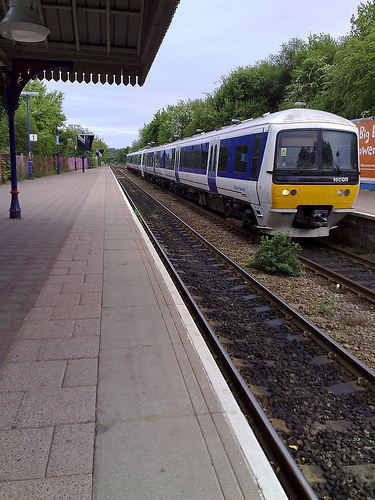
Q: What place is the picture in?
A: It is at the station.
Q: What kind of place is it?
A: It is a station.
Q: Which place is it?
A: It is a station.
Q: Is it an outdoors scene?
A: Yes, it is outdoors.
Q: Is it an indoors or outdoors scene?
A: It is outdoors.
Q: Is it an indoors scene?
A: No, it is outdoors.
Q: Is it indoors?
A: No, it is outdoors.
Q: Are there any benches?
A: No, there are no benches.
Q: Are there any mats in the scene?
A: No, there are no mats.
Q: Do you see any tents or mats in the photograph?
A: No, there are no mats or tents.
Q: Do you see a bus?
A: No, there are no buses.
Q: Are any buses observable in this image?
A: No, there are no buses.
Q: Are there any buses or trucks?
A: No, there are no buses or trucks.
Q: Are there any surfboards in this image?
A: No, there are no surfboards.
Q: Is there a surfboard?
A: No, there are no surfboards.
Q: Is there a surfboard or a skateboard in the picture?
A: No, there are no surfboards or skateboards.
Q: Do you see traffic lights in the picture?
A: No, there are no traffic lights.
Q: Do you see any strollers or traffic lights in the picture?
A: No, there are no traffic lights or strollers.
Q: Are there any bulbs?
A: No, there are no bulbs.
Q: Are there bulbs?
A: No, there are no bulbs.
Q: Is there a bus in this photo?
A: No, there are no buses.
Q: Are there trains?
A: Yes, there is a train.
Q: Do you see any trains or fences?
A: Yes, there is a train.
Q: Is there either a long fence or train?
A: Yes, there is a long train.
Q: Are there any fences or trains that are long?
A: Yes, the train is long.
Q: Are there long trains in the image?
A: Yes, there is a long train.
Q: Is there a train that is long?
A: Yes, there is a train that is long.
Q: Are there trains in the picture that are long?
A: Yes, there is a train that is long.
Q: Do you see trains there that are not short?
A: Yes, there is a long train.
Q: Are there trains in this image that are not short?
A: Yes, there is a long train.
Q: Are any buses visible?
A: No, there are no buses.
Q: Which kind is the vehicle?
A: The vehicle is a train.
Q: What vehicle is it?
A: The vehicle is a train.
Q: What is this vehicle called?
A: That is a train.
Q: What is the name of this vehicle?
A: That is a train.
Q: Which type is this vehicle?
A: That is a train.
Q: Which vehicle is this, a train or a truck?
A: That is a train.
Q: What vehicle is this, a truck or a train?
A: That is a train.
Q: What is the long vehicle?
A: The vehicle is a train.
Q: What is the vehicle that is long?
A: The vehicle is a train.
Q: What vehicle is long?
A: The vehicle is a train.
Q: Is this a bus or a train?
A: This is a train.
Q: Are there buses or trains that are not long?
A: No, there is a train but it is long.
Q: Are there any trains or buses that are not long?
A: No, there is a train but it is long.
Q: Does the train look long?
A: Yes, the train is long.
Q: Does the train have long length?
A: Yes, the train is long.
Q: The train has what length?
A: The train is long.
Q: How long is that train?
A: The train is long.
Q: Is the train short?
A: No, the train is long.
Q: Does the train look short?
A: No, the train is long.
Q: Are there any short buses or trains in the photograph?
A: No, there is a train but it is long.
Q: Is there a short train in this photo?
A: No, there is a train but it is long.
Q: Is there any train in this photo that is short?
A: No, there is a train but it is long.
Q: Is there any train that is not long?
A: No, there is a train but it is long.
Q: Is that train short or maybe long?
A: The train is long.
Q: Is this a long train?
A: Yes, this is a long train.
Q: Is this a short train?
A: No, this is a long train.